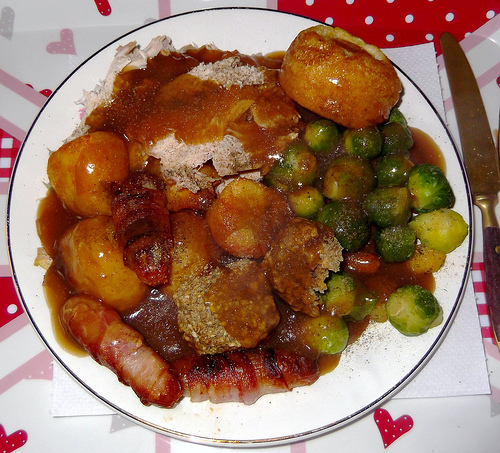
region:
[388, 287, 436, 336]
Small green veggie on a plate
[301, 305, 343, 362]
Small green veggie on a plate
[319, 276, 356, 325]
Small green veggie on a plate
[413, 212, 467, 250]
Small green veggie on a plate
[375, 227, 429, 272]
Small green veggie on a plate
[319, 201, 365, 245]
Small green veggie on a plate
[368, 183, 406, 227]
Small green veggie on a plate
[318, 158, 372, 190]
Small green veggie on a plate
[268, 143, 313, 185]
Small green veggie on a plate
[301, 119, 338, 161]
Small green veggie on a plate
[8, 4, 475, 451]
A white plate with food on it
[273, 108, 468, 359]
Green brussel sprouts with sauce on a plate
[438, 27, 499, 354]
A silver, brown, and gold knife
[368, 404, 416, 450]
A red and white heart decoration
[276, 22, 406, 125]
A piece of bread on a plate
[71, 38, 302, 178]
Some kind of meat on a white plate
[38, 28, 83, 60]
A pink and white heart decoration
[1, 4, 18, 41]
A gray and white heart decoration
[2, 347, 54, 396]
A pink stripe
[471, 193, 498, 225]
The gold part of a knife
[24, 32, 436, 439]
a big plate of food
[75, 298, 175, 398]
a little piece of sausage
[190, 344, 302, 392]
a little piece of bacon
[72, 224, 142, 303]
a little piece of potato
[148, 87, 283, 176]
a little piece of bread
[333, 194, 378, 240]
a little piece of brussel sprouts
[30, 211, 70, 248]
a little bit of sauce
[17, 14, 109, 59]
a heart pattern on a tableclothe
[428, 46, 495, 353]
a really thick butter knife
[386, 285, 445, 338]
green food on plate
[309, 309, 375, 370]
green food on plate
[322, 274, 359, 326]
green food on plate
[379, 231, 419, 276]
green food on plate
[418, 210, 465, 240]
green food on plate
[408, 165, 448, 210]
green food on plate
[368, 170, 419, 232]
green food on plate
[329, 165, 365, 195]
green food on plate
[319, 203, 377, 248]
green food on plate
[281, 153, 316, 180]
green food on plate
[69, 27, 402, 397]
Food is on the plate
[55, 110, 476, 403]
the plate is white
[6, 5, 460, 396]
the plate is round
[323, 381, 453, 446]
hearts on the cloth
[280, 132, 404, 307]
the vegetables are green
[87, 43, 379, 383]
the sauce is orange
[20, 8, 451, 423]
A plate is on the table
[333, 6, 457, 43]
the tablecloth is red and white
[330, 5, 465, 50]
table cloth is polka dotted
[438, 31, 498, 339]
dinner knife sitting near a plate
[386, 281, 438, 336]
cooked Brussel sprout on a plate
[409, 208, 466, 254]
cooked Brussel sprout on a plate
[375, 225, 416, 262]
cooked Brussel sprout on a plate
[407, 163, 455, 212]
cooked Brussel sprout on a plate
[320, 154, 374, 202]
cooked Brussel sprout on a plate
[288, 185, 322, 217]
cooked Brussel sprout on a plate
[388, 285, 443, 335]
the brussel sprout is cooked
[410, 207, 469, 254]
the brussel sprout is cooked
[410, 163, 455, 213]
the brussel sprout is cooked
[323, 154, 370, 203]
the brussel sprout is cooked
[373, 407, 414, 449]
the heart is red